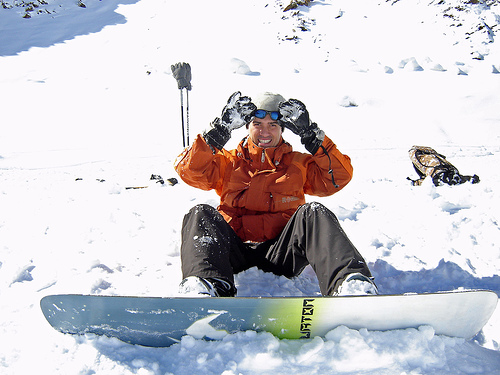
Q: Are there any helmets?
A: No, there are no helmets.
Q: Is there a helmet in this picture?
A: No, there are no helmets.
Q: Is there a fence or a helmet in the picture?
A: No, there are no helmets or fences.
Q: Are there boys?
A: No, there are no boys.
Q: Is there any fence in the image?
A: No, there are no fences.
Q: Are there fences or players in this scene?
A: No, there are no fences or players.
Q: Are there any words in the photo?
A: Yes, there are words.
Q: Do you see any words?
A: Yes, there are words.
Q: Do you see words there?
A: Yes, there are words.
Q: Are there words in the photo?
A: Yes, there are words.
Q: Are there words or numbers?
A: Yes, there are words.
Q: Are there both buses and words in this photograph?
A: No, there are words but no buses.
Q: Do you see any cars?
A: No, there are no cars.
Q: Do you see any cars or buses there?
A: No, there are no cars or buses.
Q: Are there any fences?
A: No, there are no fences.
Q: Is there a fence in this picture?
A: No, there are no fences.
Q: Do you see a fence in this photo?
A: No, there are no fences.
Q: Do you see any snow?
A: Yes, there is snow.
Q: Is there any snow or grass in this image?
A: Yes, there is snow.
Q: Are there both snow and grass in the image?
A: No, there is snow but no grass.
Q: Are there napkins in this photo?
A: No, there are no napkins.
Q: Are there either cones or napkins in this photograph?
A: No, there are no napkins or cones.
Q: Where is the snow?
A: The snow is on the ground.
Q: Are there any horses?
A: No, there are no horses.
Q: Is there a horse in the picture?
A: No, there are no horses.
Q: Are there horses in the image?
A: No, there are no horses.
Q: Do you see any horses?
A: No, there are no horses.